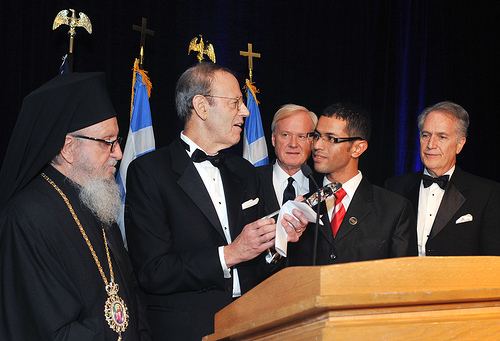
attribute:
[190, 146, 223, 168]
bowtie — black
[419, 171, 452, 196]
bowtie — black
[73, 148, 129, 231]
beard — long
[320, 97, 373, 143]
hair — black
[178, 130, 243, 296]
shirt — white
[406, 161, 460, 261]
shirt — white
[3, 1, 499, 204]
curtain — blue, black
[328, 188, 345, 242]
tie — red, golden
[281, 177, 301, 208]
tie — black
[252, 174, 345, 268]
award — glass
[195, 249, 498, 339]
podium — wood, large, oak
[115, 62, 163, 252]
flag — blue, white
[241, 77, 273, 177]
flag — blue, white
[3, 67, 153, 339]
priest — orthodox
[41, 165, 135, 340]
necklace — gold, large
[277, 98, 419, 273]
man — black, african american, young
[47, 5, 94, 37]
eagle — gold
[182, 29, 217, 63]
eagle — gold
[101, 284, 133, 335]
medallion — large, round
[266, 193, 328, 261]
item — white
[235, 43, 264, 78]
cross — gold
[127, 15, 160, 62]
cross — gold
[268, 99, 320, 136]
hair — blonde